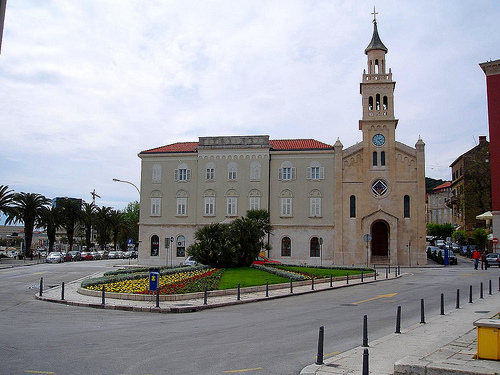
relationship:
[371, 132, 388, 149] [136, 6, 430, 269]
clock on front of building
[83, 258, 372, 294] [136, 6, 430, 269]
flower bed in front of building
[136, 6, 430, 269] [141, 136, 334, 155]
building has roof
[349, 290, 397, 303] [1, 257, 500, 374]
arrow on street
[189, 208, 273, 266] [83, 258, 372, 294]
bush in flower bed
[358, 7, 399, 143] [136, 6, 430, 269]
tower on building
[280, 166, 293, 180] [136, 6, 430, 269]
window on building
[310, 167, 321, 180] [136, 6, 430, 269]
window on building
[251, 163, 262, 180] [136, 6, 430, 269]
window on building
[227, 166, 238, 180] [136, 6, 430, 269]
window on building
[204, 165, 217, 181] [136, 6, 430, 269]
window on building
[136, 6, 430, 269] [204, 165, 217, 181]
building has window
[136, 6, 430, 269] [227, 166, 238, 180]
building has window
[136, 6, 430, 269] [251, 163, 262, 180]
building has window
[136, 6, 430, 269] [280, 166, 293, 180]
building has window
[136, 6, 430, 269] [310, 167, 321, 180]
building has window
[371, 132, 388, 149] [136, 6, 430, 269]
clock on building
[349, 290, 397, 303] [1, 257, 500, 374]
arrow in street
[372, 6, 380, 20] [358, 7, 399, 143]
cross on top of tower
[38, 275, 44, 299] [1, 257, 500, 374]
post on side of street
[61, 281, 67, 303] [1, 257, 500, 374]
post on side of street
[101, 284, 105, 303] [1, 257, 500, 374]
post on side of street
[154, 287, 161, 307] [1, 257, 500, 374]
post on side of street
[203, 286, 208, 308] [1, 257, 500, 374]
post on side of street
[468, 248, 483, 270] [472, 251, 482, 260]
man wearing shirt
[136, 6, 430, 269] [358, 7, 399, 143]
building has tower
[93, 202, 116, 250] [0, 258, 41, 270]
tree on sidewalk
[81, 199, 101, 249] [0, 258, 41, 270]
tree on sidewalk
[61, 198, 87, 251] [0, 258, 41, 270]
tree on sidewalk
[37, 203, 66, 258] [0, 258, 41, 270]
tree on sidewalk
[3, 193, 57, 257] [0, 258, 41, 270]
tree on sidewalk